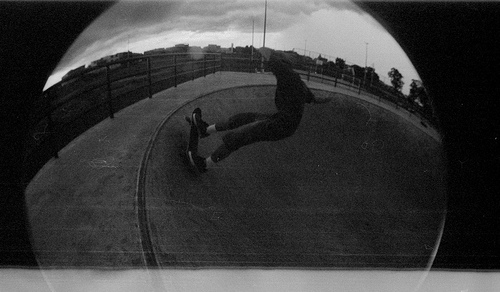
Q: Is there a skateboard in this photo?
A: Yes, there is a skateboard.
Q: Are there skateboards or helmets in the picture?
A: Yes, there is a skateboard.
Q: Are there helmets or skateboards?
A: Yes, there is a skateboard.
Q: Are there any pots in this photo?
A: No, there are no pots.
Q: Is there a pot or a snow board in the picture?
A: No, there are no pots or snowboards.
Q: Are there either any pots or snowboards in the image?
A: No, there are no pots or snowboards.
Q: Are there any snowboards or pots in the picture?
A: No, there are no pots or snowboards.